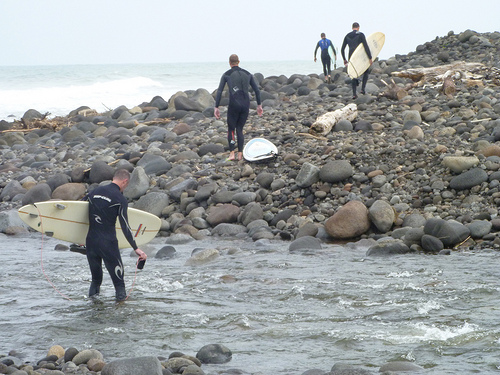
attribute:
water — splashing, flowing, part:
[206, 247, 457, 340]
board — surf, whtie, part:
[14, 185, 166, 292]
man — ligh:
[91, 168, 144, 274]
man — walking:
[221, 67, 261, 165]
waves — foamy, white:
[177, 254, 340, 320]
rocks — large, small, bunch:
[322, 145, 471, 256]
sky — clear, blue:
[86, 14, 262, 119]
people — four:
[223, 7, 405, 131]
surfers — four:
[213, 13, 432, 168]